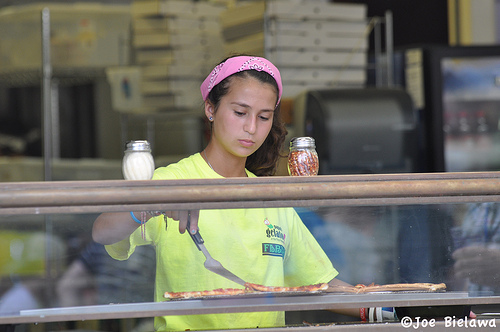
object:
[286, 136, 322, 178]
shaker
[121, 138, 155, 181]
jar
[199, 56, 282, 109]
headband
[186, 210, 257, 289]
spatula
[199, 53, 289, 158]
hair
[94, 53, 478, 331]
girl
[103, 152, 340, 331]
shirt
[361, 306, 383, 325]
wristband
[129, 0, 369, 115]
box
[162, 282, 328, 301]
pizza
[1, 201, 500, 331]
glass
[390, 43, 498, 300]
fridge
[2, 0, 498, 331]
restaurant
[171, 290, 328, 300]
tray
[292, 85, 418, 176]
dispencer